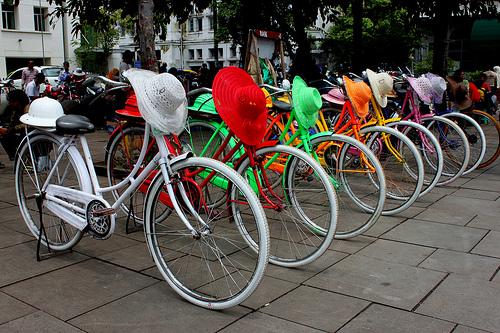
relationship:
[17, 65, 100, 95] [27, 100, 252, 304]
people behind bike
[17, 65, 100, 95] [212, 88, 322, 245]
people behind bike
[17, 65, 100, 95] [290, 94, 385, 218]
people behind bike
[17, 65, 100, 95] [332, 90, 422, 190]
people behind bike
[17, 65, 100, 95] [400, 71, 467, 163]
people behind bike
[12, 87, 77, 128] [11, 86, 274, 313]
hat on back bike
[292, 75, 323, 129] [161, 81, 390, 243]
green hat on back bike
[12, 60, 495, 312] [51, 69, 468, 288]
row of bicycles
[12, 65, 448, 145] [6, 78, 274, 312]
hat on bicycle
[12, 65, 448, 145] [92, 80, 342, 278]
hat on bicycle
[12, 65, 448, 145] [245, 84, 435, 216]
hat on bicycle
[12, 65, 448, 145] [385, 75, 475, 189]
hat on bicycle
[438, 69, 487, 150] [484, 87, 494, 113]
man wearing backpack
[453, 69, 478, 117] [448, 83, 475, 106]
man wearing shirt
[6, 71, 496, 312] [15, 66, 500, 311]
line of bicycle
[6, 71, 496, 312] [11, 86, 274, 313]
line of bike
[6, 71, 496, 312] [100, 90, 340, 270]
line of bike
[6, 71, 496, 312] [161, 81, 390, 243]
line of bike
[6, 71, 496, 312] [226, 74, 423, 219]
line of bike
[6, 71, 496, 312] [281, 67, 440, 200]
line of bike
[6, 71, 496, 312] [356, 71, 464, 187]
line of bike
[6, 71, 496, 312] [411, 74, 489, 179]
line of bike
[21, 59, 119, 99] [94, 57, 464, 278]
people behind bikes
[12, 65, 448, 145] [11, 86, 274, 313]
hat on bike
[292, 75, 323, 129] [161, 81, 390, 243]
green hat on bike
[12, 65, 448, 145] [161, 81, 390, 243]
hat on bike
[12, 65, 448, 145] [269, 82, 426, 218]
hat on bike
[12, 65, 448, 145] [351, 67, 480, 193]
hat on bike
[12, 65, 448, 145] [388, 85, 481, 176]
hat on bike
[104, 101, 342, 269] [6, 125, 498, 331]
bicycle on sidewalk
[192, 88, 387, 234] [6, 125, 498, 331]
bicycle on sidewalk